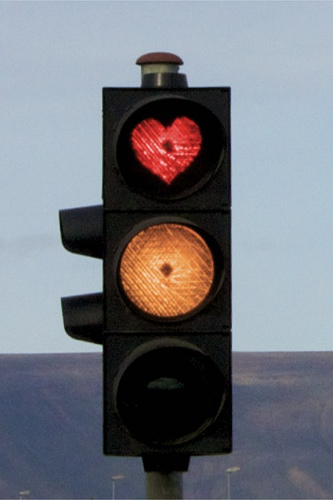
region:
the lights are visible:
[71, 52, 263, 485]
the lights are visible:
[40, 69, 209, 323]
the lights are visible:
[74, 15, 234, 268]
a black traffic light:
[42, 37, 251, 485]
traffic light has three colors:
[36, 32, 263, 481]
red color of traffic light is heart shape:
[121, 98, 215, 204]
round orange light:
[108, 217, 226, 328]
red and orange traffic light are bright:
[95, 92, 235, 323]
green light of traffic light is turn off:
[102, 338, 231, 465]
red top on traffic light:
[132, 45, 192, 92]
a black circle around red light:
[107, 90, 229, 207]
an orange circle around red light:
[99, 209, 229, 334]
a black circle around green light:
[106, 333, 233, 454]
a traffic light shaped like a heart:
[91, 88, 247, 246]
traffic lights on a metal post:
[37, 46, 279, 498]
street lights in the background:
[5, 461, 258, 496]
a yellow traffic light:
[92, 208, 226, 338]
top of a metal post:
[74, 26, 237, 109]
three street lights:
[2, 460, 292, 496]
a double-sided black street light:
[26, 78, 258, 480]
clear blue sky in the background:
[5, 11, 326, 226]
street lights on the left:
[32, 168, 112, 383]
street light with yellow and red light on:
[85, 77, 265, 486]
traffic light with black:
[62, 47, 267, 499]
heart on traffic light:
[128, 117, 200, 194]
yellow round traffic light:
[109, 221, 217, 317]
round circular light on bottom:
[104, 344, 209, 432]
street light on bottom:
[218, 465, 245, 498]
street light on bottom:
[98, 470, 129, 498]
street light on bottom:
[13, 481, 35, 496]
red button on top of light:
[118, 42, 184, 83]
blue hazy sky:
[254, 271, 316, 336]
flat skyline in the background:
[230, 348, 304, 401]